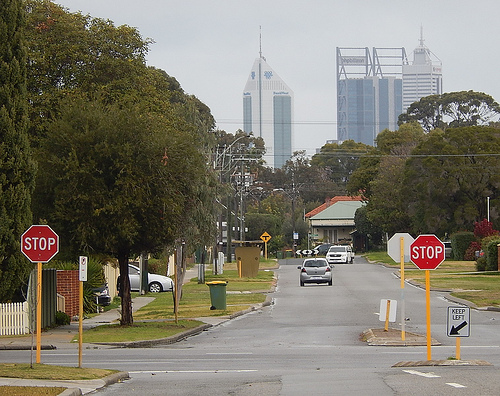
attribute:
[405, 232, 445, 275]
stop sign — red, on right side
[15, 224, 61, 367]
stop sign — on left side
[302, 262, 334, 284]
car — grey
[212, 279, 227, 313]
trash can — green, yellow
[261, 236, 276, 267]
sign — yellow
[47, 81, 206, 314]
tree — big, tall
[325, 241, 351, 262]
van — white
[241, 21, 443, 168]
buildings — tall, in distance, white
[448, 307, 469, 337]
sign — black, white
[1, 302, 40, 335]
fence — white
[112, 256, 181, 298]
car — white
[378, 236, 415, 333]
signs — opposite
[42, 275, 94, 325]
fence — brick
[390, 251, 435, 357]
poles — yellow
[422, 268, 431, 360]
pole — yellow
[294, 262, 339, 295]
vehicle — silver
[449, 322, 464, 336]
arrow — black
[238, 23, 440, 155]
skyscrapers — in background